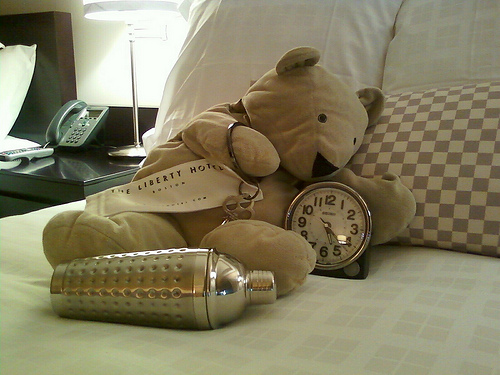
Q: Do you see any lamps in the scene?
A: Yes, there is a lamp.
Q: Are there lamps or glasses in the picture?
A: Yes, there is a lamp.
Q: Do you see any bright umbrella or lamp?
A: Yes, there is a bright lamp.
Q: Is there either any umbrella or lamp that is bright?
A: Yes, the lamp is bright.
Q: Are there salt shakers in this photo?
A: No, there are no salt shakers.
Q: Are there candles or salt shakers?
A: No, there are no salt shakers or candles.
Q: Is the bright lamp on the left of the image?
A: Yes, the lamp is on the left of the image.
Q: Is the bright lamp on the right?
A: No, the lamp is on the left of the image.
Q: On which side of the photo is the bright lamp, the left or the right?
A: The lamp is on the left of the image.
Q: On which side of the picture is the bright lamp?
A: The lamp is on the left of the image.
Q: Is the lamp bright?
A: Yes, the lamp is bright.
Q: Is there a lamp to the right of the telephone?
A: Yes, there is a lamp to the right of the telephone.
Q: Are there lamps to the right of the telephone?
A: Yes, there is a lamp to the right of the telephone.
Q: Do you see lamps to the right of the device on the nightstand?
A: Yes, there is a lamp to the right of the telephone.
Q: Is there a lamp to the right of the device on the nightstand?
A: Yes, there is a lamp to the right of the telephone.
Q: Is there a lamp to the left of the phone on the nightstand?
A: No, the lamp is to the right of the phone.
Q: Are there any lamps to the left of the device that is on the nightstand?
A: No, the lamp is to the right of the phone.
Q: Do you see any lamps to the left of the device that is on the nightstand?
A: No, the lamp is to the right of the phone.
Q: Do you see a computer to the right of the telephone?
A: No, there is a lamp to the right of the telephone.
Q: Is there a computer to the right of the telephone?
A: No, there is a lamp to the right of the telephone.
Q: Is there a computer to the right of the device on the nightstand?
A: No, there is a lamp to the right of the telephone.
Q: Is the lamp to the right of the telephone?
A: Yes, the lamp is to the right of the telephone.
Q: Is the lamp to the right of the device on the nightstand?
A: Yes, the lamp is to the right of the telephone.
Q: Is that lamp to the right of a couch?
A: No, the lamp is to the right of the telephone.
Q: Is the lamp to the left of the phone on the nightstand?
A: No, the lamp is to the right of the telephone.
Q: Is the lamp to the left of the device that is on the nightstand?
A: No, the lamp is to the right of the telephone.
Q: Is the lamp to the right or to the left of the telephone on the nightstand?
A: The lamp is to the right of the phone.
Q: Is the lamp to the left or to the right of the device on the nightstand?
A: The lamp is to the right of the phone.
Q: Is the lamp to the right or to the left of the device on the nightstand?
A: The lamp is to the right of the phone.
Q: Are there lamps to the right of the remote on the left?
A: Yes, there is a lamp to the right of the remote control.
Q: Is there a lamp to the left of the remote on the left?
A: No, the lamp is to the right of the remote.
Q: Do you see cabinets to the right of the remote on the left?
A: No, there is a lamp to the right of the remote.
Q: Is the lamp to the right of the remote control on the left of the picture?
A: Yes, the lamp is to the right of the remote control.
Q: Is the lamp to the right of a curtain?
A: No, the lamp is to the right of the remote control.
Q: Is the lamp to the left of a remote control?
A: No, the lamp is to the right of a remote control.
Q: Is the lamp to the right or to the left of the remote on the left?
A: The lamp is to the right of the remote.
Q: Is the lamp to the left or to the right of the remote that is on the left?
A: The lamp is to the right of the remote.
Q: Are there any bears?
A: Yes, there is a bear.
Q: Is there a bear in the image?
A: Yes, there is a bear.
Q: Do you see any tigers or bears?
A: Yes, there is a bear.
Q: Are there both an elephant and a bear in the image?
A: No, there is a bear but no elephants.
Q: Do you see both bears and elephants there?
A: No, there is a bear but no elephants.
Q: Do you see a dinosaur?
A: No, there are no dinosaurs.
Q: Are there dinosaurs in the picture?
A: No, there are no dinosaurs.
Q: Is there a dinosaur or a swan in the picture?
A: No, there are no dinosaurs or swans.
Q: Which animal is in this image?
A: The animal is a bear.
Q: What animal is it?
A: The animal is a bear.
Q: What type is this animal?
A: That is a bear.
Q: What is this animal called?
A: That is a bear.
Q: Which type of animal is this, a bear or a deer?
A: That is a bear.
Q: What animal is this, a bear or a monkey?
A: This is a bear.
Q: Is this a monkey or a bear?
A: This is a bear.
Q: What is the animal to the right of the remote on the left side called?
A: The animal is a bear.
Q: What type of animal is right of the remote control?
A: The animal is a bear.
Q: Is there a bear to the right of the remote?
A: Yes, there is a bear to the right of the remote.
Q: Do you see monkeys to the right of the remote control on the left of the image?
A: No, there is a bear to the right of the remote control.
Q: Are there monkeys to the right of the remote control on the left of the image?
A: No, there is a bear to the right of the remote control.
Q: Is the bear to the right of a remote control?
A: Yes, the bear is to the right of a remote control.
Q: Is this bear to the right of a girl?
A: No, the bear is to the right of a remote control.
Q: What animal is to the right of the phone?
A: The animal is a bear.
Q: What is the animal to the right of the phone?
A: The animal is a bear.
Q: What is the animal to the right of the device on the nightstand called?
A: The animal is a bear.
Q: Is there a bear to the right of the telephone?
A: Yes, there is a bear to the right of the telephone.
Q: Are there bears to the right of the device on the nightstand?
A: Yes, there is a bear to the right of the telephone.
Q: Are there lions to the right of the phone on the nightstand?
A: No, there is a bear to the right of the telephone.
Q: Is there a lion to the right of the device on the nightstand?
A: No, there is a bear to the right of the telephone.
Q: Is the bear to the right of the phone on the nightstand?
A: Yes, the bear is to the right of the phone.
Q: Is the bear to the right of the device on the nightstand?
A: Yes, the bear is to the right of the phone.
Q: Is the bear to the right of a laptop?
A: No, the bear is to the right of the phone.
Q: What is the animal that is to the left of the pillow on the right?
A: The animal is a bear.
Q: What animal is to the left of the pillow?
A: The animal is a bear.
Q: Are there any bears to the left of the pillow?
A: Yes, there is a bear to the left of the pillow.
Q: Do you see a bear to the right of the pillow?
A: No, the bear is to the left of the pillow.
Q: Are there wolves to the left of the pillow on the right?
A: No, there is a bear to the left of the pillow.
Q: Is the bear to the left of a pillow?
A: Yes, the bear is to the left of a pillow.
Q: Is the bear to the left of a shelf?
A: No, the bear is to the left of a pillow.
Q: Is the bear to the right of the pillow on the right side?
A: No, the bear is to the left of the pillow.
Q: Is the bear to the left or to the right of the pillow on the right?
A: The bear is to the left of the pillow.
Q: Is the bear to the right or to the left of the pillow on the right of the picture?
A: The bear is to the left of the pillow.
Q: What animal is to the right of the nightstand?
A: The animal is a bear.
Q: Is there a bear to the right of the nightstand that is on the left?
A: Yes, there is a bear to the right of the nightstand.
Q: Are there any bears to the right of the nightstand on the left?
A: Yes, there is a bear to the right of the nightstand.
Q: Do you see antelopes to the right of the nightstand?
A: No, there is a bear to the right of the nightstand.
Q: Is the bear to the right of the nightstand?
A: Yes, the bear is to the right of the nightstand.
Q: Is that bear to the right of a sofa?
A: No, the bear is to the right of the nightstand.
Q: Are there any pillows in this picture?
A: Yes, there is a pillow.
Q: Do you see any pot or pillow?
A: Yes, there is a pillow.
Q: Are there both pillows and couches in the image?
A: No, there is a pillow but no couches.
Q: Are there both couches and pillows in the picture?
A: No, there is a pillow but no couches.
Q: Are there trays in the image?
A: No, there are no trays.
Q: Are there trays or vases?
A: No, there are no trays or vases.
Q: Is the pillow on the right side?
A: Yes, the pillow is on the right of the image.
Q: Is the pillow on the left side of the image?
A: No, the pillow is on the right of the image.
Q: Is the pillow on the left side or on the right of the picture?
A: The pillow is on the right of the image.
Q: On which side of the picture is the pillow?
A: The pillow is on the right of the image.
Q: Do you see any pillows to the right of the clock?
A: Yes, there is a pillow to the right of the clock.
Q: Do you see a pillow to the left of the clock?
A: No, the pillow is to the right of the clock.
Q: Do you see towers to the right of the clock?
A: No, there is a pillow to the right of the clock.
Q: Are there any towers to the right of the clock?
A: No, there is a pillow to the right of the clock.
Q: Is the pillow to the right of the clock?
A: Yes, the pillow is to the right of the clock.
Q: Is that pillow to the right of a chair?
A: No, the pillow is to the right of the clock.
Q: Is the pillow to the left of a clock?
A: No, the pillow is to the right of a clock.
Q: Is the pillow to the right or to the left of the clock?
A: The pillow is to the right of the clock.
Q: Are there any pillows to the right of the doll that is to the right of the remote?
A: Yes, there is a pillow to the right of the doll.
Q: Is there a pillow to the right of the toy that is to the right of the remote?
A: Yes, there is a pillow to the right of the doll.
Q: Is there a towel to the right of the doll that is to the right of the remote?
A: No, there is a pillow to the right of the doll.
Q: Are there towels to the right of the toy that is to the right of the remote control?
A: No, there is a pillow to the right of the doll.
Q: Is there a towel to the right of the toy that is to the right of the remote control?
A: No, there is a pillow to the right of the doll.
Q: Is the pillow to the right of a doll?
A: Yes, the pillow is to the right of a doll.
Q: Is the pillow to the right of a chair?
A: No, the pillow is to the right of a doll.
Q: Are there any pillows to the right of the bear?
A: Yes, there is a pillow to the right of the bear.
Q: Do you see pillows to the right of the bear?
A: Yes, there is a pillow to the right of the bear.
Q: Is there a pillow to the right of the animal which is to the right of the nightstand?
A: Yes, there is a pillow to the right of the bear.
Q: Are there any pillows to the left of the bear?
A: No, the pillow is to the right of the bear.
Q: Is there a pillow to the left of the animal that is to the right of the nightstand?
A: No, the pillow is to the right of the bear.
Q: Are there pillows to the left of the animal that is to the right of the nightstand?
A: No, the pillow is to the right of the bear.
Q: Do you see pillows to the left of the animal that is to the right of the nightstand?
A: No, the pillow is to the right of the bear.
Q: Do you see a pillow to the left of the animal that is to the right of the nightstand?
A: No, the pillow is to the right of the bear.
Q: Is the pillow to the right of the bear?
A: Yes, the pillow is to the right of the bear.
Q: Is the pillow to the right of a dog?
A: No, the pillow is to the right of the bear.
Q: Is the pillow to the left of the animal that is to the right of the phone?
A: No, the pillow is to the right of the bear.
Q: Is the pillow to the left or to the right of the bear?
A: The pillow is to the right of the bear.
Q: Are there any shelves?
A: No, there are no shelves.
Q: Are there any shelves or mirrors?
A: No, there are no shelves or mirrors.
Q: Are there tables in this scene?
A: Yes, there is a table.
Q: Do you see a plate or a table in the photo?
A: Yes, there is a table.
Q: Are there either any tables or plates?
A: Yes, there is a table.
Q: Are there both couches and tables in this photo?
A: No, there is a table but no couches.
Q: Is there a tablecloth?
A: No, there are no tablecloths.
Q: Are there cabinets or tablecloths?
A: No, there are no tablecloths or cabinets.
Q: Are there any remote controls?
A: Yes, there is a remote control.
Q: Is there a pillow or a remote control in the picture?
A: Yes, there is a remote control.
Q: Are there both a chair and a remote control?
A: No, there is a remote control but no chairs.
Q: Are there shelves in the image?
A: No, there are no shelves.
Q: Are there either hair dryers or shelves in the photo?
A: No, there are no shelves or hair dryers.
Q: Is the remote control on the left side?
A: Yes, the remote control is on the left of the image.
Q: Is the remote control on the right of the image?
A: No, the remote control is on the left of the image.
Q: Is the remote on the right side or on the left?
A: The remote is on the left of the image.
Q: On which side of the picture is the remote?
A: The remote is on the left of the image.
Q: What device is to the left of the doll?
A: The device is a remote control.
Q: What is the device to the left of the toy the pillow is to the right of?
A: The device is a remote control.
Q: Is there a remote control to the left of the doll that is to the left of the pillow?
A: Yes, there is a remote control to the left of the doll.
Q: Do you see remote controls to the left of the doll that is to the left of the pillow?
A: Yes, there is a remote control to the left of the doll.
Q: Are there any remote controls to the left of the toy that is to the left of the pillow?
A: Yes, there is a remote control to the left of the doll.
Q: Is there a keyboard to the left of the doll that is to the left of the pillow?
A: No, there is a remote control to the left of the doll.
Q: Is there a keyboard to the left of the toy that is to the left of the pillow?
A: No, there is a remote control to the left of the doll.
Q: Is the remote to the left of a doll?
A: Yes, the remote is to the left of a doll.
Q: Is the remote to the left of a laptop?
A: No, the remote is to the left of a doll.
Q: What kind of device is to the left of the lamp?
A: The device is a remote control.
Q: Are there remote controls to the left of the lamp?
A: Yes, there is a remote control to the left of the lamp.